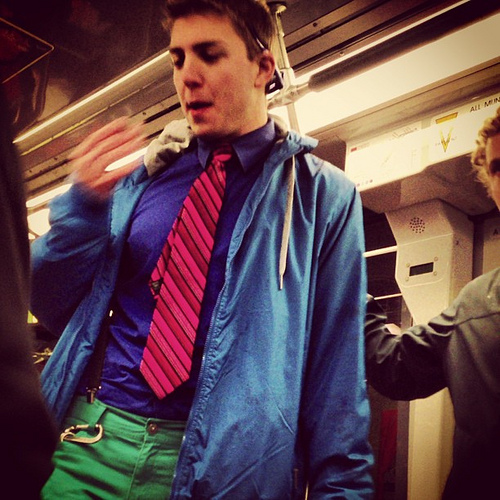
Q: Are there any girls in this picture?
A: No, there are no girls.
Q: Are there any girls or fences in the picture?
A: No, there are no girls or fences.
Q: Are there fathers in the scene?
A: No, there are no fathers.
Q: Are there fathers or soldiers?
A: No, there are no fathers or soldiers.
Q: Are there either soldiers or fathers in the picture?
A: No, there are no fathers or soldiers.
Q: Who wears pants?
A: The man wears pants.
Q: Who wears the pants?
A: The man wears pants.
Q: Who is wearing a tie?
A: The man is wearing a tie.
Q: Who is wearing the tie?
A: The man is wearing a tie.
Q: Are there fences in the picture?
A: No, there are no fences.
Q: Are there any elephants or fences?
A: No, there are no fences or elephants.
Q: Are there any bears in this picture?
A: No, there are no bears.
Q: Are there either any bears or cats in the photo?
A: No, there are no bears or cats.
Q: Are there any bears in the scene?
A: No, there are no bears.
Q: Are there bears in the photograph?
A: No, there are no bears.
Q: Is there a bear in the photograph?
A: No, there are no bears.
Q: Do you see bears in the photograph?
A: No, there are no bears.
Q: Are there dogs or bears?
A: No, there are no bears or dogs.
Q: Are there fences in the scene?
A: No, there are no fences.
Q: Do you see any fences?
A: No, there are no fences.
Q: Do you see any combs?
A: No, there are no combs.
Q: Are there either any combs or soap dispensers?
A: No, there are no combs or soap dispensers.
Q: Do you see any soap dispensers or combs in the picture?
A: No, there are no combs or soap dispensers.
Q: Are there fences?
A: No, there are no fences.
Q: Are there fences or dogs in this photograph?
A: No, there are no fences or dogs.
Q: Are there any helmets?
A: No, there are no helmets.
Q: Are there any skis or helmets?
A: No, there are no helmets or skis.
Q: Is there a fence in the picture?
A: No, there are no fences.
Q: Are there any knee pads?
A: No, there are no knee pads.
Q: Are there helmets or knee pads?
A: No, there are no knee pads or helmets.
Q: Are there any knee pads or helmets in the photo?
A: No, there are no knee pads or helmets.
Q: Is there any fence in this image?
A: No, there are no fences.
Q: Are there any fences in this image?
A: No, there are no fences.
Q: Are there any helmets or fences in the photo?
A: No, there are no fences or helmets.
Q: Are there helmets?
A: No, there are no helmets.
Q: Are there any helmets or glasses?
A: No, there are no helmets or glasses.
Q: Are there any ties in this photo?
A: Yes, there is a tie.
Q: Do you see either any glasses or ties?
A: Yes, there is a tie.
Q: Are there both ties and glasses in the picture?
A: No, there is a tie but no glasses.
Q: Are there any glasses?
A: No, there are no glasses.